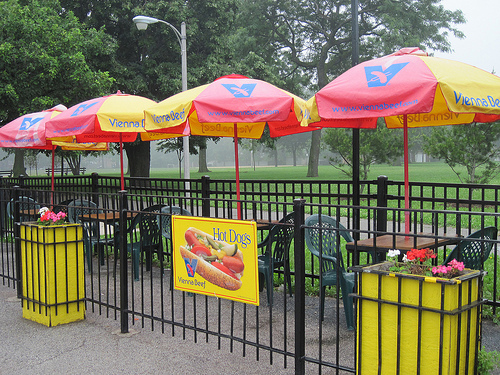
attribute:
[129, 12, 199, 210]
post — Lamp 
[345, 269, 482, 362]
container — yellow  .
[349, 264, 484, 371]
container — yellow  .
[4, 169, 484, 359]
fences — two .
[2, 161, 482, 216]
lawn — open., background.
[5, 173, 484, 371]
fence — beside , Wrought iron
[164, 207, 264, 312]
advertisement — Hot dog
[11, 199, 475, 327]
table — over 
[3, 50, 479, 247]
umbrellas — multicolored 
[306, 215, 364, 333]
chair — green plastic 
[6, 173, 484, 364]
post — black metal fence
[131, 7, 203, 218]
light — tall street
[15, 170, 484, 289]
area — seating 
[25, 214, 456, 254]
top — brown wooden table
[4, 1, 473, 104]
foliage — green 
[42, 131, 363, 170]
fog — in the background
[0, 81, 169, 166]
umbrella — yellow, red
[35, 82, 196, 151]
umbrella — red, yellow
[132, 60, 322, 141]
umbrella — yellow, open, red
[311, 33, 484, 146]
umbrella — open, red, yellow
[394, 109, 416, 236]
pole — red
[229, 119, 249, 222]
pole — red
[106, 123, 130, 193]
pole — red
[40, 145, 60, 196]
pole — red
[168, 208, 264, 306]
sign — yellow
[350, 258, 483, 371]
flower pot — yellow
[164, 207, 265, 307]
advertisement sign — hot dog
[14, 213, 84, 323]
container — yellow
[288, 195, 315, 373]
fence post — metal, black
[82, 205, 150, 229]
table top — wooden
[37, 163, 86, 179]
bench — wooden slat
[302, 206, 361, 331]
plastic chair — green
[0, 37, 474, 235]
umbrellas — Open red ., yellow  ., multicolored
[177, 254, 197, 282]
logo — Vienna Beef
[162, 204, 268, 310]
sign — Advertising 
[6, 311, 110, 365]
cracks — asphalt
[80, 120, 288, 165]
fog — in the background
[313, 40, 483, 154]
umbrella — yellow, red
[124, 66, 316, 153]
umbrella — red, yellow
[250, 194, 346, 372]
rails — black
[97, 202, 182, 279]
chair — blue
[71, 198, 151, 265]
table — brown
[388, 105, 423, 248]
pole — red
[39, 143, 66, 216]
pole — red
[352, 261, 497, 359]
container — yellow